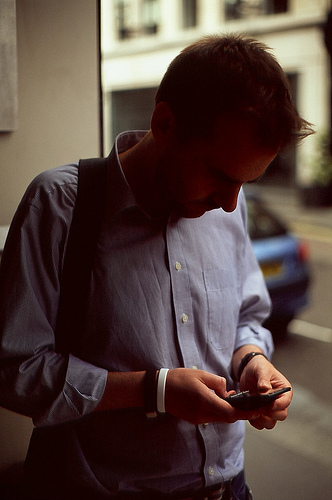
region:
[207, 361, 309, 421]
The man is holding a cell phone.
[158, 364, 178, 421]
The man has a white bracelet on.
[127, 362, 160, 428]
The man has a brown bracelet on.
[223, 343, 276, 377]
The man is wearing a watch.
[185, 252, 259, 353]
There is a pocket on the man's shirt.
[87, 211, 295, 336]
The shirt is blue.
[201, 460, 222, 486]
The buttons on the shirt are white.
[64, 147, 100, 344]
The man has a strap over the shoulder.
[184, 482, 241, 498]
The man is wearing a belt.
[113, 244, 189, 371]
There are wrinkles on the shirt.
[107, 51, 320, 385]
A man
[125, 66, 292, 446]
A man with a phone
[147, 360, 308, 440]
two hands holding a phone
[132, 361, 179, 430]
A white band on a wrist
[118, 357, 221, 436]
A black band on a wrist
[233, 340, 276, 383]
Awatch on a wrist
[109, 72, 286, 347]
A man wearing a blue shirt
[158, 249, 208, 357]
White buttons on a blue shirt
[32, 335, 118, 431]
A rolled up sleeve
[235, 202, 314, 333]
The back of a blue car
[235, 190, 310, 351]
blue car outside the window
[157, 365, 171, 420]
white bracelet on right wrist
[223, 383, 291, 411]
cell phone in man's hand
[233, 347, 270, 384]
watch on the man's left wrist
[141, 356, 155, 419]
black bracelet on right arm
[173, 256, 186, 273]
white button on the man's shirt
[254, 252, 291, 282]
yellow license plate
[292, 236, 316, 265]
the red tail light of the car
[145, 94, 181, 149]
the man's right ear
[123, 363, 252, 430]
the man's right hand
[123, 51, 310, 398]
man looking at cell phone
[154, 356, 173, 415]
white bracelet on wrist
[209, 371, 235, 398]
thumb pushing button on phone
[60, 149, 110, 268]
black strap on shoulder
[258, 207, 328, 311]
back of blue car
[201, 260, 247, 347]
breast pocket on shirt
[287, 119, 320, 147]
man's hair sticking up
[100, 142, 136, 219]
shirt collar around neck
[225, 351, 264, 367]
band and buckle on watch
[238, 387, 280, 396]
screen on cell phone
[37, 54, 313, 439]
man using a cell phone.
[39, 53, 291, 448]
man looking at a cell phone.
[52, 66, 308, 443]
man checking into a cell phone.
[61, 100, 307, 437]
person using a cell phone.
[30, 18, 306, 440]
person holding a cell phone.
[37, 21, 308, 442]
person looking at his cell phone.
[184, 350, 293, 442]
hands holding a cell phone.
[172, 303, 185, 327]
white button on a shirt.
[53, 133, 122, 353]
a dark shoulder strap.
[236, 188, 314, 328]
rear end of a vehicle.